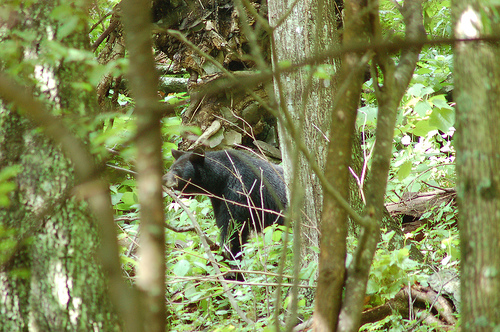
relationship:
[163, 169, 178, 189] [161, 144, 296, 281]
snout of bear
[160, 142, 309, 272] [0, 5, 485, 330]
bear standing among trees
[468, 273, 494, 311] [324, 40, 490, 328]
bark of a tree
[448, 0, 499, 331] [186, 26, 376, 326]
trunk of a tree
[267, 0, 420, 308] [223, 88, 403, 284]
trunk of a tree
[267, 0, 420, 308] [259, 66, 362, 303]
trunk of a tree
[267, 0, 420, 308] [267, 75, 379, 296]
trunk of a tree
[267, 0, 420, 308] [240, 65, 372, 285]
trunk of a tree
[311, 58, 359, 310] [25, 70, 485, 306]
trunk of a tree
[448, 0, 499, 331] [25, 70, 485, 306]
trunk of a tree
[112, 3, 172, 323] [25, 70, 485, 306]
trunk of a tree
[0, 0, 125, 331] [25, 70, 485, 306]
trunk of a tree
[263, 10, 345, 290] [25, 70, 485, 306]
trunk of a tree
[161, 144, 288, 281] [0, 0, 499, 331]
bear in a natural habitat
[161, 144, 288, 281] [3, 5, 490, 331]
bear in natural habitat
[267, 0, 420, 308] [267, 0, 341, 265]
trunk with lichen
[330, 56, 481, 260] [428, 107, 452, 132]
frond of frond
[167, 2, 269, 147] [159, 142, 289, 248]
hillside above bear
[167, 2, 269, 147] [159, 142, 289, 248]
hillside behind bear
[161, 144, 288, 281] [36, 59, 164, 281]
bear in area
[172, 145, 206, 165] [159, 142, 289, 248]
ears of bear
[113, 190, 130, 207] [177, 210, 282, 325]
leaves in bushes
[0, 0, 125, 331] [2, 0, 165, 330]
trunk of tree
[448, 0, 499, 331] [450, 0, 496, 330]
trunk of tree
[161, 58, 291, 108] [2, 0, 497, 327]
twig reaching across frame